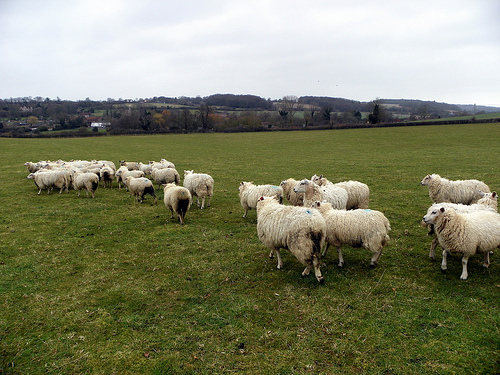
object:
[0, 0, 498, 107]
sky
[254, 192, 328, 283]
sheep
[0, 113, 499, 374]
grass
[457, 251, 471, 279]
leg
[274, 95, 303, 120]
trees